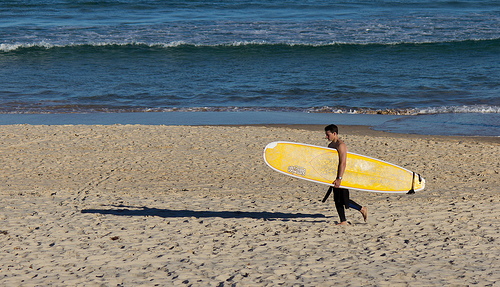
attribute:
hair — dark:
[322, 119, 343, 139]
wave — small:
[10, 25, 487, 63]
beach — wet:
[153, 109, 269, 124]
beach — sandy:
[1, 0, 498, 285]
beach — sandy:
[0, 112, 492, 284]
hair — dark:
[314, 110, 359, 147]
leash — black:
[409, 169, 415, 195]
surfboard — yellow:
[260, 139, 427, 193]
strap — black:
[402, 170, 421, 201]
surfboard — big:
[262, 141, 429, 196]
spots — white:
[286, 147, 408, 192]